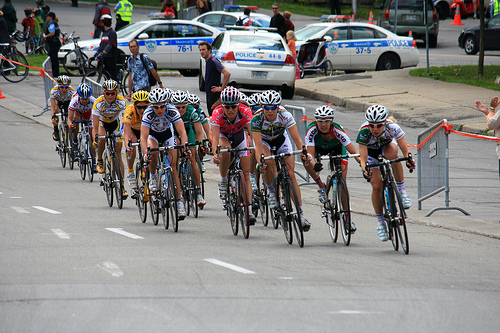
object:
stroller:
[295, 37, 333, 78]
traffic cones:
[368, 11, 374, 25]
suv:
[381, 0, 439, 47]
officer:
[114, 0, 134, 31]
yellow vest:
[115, 0, 133, 24]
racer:
[305, 104, 361, 245]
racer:
[140, 87, 188, 232]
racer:
[250, 89, 314, 248]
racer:
[246, 93, 281, 230]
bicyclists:
[355, 104, 416, 254]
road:
[0, 76, 500, 333]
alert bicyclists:
[49, 75, 416, 255]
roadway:
[0, 105, 500, 333]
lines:
[0, 193, 383, 333]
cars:
[210, 25, 295, 99]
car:
[199, 30, 296, 99]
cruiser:
[58, 12, 222, 77]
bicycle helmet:
[364, 104, 389, 123]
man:
[198, 41, 232, 116]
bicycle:
[260, 145, 309, 248]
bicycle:
[365, 152, 415, 254]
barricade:
[417, 119, 470, 217]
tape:
[406, 122, 500, 151]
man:
[189, 36, 231, 116]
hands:
[211, 86, 223, 94]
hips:
[213, 88, 221, 97]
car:
[190, 4, 271, 31]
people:
[235, 8, 252, 31]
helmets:
[220, 86, 241, 107]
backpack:
[140, 53, 157, 87]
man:
[127, 40, 164, 102]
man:
[82, 14, 131, 97]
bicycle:
[81, 59, 157, 96]